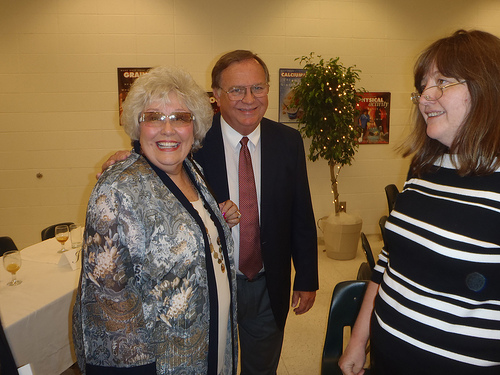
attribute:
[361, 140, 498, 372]
shirt — white, blue, striped, black and white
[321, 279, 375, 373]
chair — black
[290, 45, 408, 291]
tree — potted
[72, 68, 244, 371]
woman — older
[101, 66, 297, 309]
woman — smiling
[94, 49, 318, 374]
man — older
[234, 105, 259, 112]
smile — big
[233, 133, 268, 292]
tie — long, burgundy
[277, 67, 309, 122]
poster — multi colored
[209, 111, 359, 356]
suit — navy blue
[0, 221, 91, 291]
glasses — semi filled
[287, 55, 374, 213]
tree — green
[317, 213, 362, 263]
planter — white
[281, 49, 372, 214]
tree — lit up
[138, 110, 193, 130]
glasses — square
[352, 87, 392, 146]
poster — multi colored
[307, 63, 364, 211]
lights — white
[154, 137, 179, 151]
lipstick — red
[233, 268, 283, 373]
pants — grey